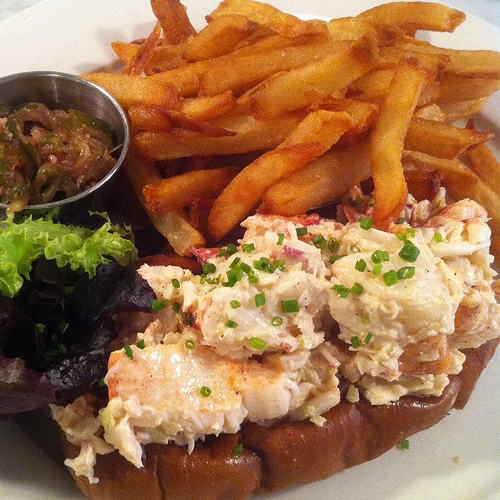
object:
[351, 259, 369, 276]
onions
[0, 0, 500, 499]
plate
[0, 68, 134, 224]
container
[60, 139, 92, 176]
peppers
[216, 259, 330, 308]
toppings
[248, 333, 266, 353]
food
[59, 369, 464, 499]
bun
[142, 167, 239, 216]
fry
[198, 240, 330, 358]
tuna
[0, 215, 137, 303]
lettuce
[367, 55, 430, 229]
fries